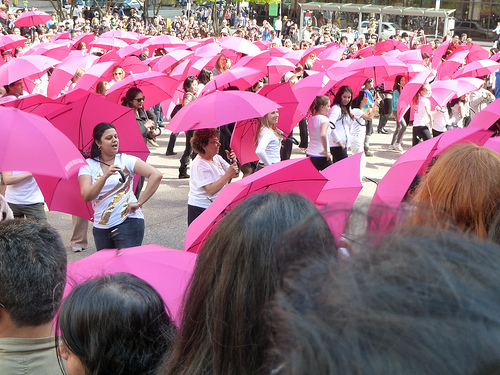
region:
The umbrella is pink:
[65, 234, 200, 314]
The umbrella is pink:
[178, 149, 321, 241]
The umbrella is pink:
[311, 145, 370, 237]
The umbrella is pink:
[368, 126, 439, 233]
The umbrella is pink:
[435, 112, 493, 149]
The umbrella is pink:
[0, 100, 80, 182]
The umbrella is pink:
[165, 88, 276, 128]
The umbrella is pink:
[32, 78, 152, 215]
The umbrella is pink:
[236, 78, 297, 156]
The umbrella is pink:
[101, 65, 181, 110]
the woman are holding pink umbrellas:
[66, 26, 339, 361]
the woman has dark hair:
[216, 218, 343, 317]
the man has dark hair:
[10, 225, 52, 339]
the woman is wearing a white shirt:
[74, 150, 226, 244]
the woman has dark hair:
[85, 113, 140, 175]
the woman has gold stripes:
[75, 161, 185, 248]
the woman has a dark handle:
[74, 142, 156, 196]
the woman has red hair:
[409, 155, 491, 207]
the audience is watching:
[154, 9, 255, 50]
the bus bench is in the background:
[291, 1, 469, 46]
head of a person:
[90, 118, 125, 160]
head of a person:
[189, 123, 233, 160]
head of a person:
[310, 83, 337, 121]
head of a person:
[259, 98, 291, 129]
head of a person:
[386, 65, 416, 86]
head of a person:
[357, 72, 377, 92]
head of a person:
[407, 78, 444, 103]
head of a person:
[5, 208, 89, 316]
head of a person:
[40, 253, 210, 373]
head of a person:
[167, 152, 379, 367]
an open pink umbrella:
[183, 155, 328, 253]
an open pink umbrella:
[60, 245, 199, 326]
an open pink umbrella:
[318, 151, 365, 248]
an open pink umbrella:
[368, 135, 439, 239]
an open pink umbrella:
[438, 127, 494, 153]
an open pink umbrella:
[397, 70, 433, 122]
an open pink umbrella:
[430, 78, 458, 113]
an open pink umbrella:
[454, 75, 484, 104]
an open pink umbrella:
[458, 58, 498, 78]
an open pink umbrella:
[438, 52, 468, 79]